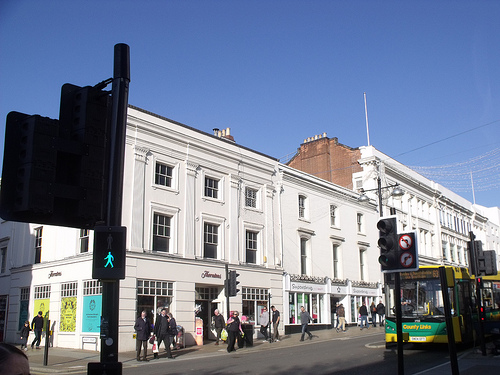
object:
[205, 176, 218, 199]
window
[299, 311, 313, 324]
jacket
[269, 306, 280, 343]
man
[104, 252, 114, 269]
green man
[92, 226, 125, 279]
traffic signal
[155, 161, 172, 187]
window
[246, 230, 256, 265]
window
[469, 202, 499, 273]
building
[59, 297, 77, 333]
poster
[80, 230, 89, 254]
window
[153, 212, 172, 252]
window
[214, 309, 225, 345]
people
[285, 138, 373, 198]
brown wall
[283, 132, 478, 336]
building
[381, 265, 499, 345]
bus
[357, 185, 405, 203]
street light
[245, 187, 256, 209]
window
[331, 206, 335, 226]
window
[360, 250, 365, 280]
window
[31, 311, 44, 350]
man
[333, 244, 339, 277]
windows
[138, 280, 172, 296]
windows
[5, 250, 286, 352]
store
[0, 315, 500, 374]
street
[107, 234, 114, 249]
man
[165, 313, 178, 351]
person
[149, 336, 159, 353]
bag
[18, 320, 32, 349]
men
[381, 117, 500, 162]
line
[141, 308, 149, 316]
head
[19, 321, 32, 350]
person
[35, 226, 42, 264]
window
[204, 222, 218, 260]
window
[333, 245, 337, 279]
window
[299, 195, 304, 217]
window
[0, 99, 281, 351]
building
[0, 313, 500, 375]
sidewalk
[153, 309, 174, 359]
man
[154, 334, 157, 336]
hand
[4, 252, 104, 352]
wall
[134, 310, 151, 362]
man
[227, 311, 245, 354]
man